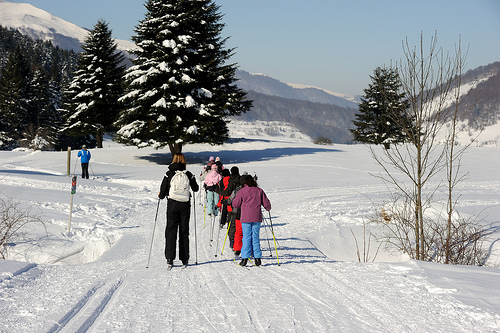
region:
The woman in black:
[139, 149, 205, 276]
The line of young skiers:
[197, 153, 284, 273]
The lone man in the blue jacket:
[70, 140, 96, 181]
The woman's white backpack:
[166, 170, 192, 207]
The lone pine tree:
[345, 59, 423, 154]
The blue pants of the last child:
[237, 221, 267, 268]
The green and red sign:
[65, 173, 79, 237]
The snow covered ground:
[0, 116, 499, 332]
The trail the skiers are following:
[0, 160, 417, 328]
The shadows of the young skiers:
[257, 215, 337, 268]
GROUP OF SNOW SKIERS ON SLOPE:
[127, 118, 322, 284]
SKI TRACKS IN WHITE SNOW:
[138, 277, 367, 327]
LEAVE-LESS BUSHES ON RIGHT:
[394, 52, 499, 261]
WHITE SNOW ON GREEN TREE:
[357, 48, 421, 142]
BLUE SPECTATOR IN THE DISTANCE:
[76, 136, 95, 181]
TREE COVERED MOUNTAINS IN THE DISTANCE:
[242, 63, 387, 140]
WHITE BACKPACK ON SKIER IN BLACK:
[156, 168, 210, 213]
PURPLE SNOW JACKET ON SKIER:
[232, 177, 269, 224]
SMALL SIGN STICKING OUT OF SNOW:
[69, 182, 95, 241]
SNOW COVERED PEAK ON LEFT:
[10, 4, 92, 34]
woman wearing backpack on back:
[161, 168, 194, 208]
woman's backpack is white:
[169, 170, 194, 205]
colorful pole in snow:
[60, 168, 80, 248]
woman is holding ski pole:
[141, 187, 166, 277]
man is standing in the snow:
[70, 138, 100, 185]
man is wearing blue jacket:
[73, 147, 96, 169]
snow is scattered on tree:
[125, 4, 236, 155]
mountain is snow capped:
[1, 1, 148, 73]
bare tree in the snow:
[357, 28, 488, 294]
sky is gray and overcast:
[3, 1, 497, 109]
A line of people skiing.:
[197, 150, 281, 269]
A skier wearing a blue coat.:
[67, 143, 102, 184]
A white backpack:
[165, 167, 195, 207]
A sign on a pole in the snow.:
[62, 172, 87, 239]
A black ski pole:
[139, 192, 161, 266]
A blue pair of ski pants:
[240, 222, 263, 260]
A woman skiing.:
[146, 150, 206, 269]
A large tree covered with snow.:
[120, 2, 228, 160]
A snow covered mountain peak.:
[2, 3, 85, 47]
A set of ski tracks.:
[52, 272, 123, 331]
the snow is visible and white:
[272, 286, 309, 311]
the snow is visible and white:
[336, 205, 389, 325]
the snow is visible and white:
[311, 143, 402, 330]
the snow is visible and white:
[360, 213, 432, 324]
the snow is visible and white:
[349, 255, 364, 332]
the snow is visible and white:
[369, 175, 467, 305]